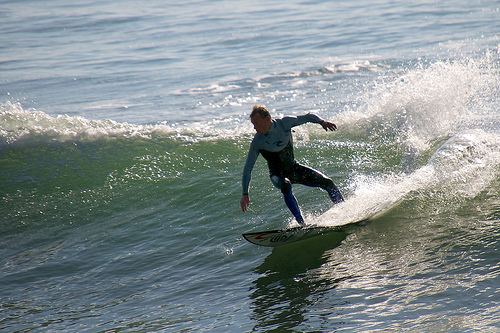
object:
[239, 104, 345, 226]
man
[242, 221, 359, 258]
surfboard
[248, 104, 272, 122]
hair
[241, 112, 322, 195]
top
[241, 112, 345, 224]
wetsuit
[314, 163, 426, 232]
wake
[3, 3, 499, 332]
water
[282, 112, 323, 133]
arm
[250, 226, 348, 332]
reflection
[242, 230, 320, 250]
bottom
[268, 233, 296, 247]
graphic design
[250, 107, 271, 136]
head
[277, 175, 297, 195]
knee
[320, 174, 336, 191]
knee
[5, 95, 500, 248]
wave